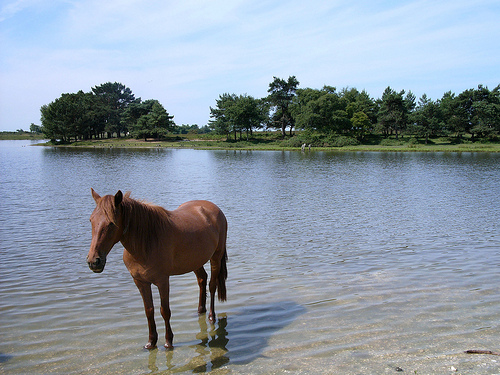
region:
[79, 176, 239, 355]
this is a horse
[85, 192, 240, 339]
the horse is brown in color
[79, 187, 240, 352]
the horse is standing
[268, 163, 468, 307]
the water is cam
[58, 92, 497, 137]
these are trees beside the water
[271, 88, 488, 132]
the trees are green in color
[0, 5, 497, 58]
the sky is light blue in color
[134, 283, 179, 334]
the horse has strong legs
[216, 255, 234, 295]
the tail is long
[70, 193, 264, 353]
the horse is in water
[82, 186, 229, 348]
Little brown pony.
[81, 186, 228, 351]
Horse standing in water.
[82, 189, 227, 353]
Little brown horse in lake.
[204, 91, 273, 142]
Tall dark green trees on bank.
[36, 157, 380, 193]
Dark calm waters of lake.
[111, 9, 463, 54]
Clear blue skies and light whispy clouds.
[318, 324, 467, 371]
Clear see through waters of lake.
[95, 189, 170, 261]
Horses beautiful brown mane.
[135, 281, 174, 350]
Two front legs of horse.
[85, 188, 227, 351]
Horse motionless in water.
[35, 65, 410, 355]
brown horse standing in the water.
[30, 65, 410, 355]
horse alone in the water.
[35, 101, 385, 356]
brown horse alone in water.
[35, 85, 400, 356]
beautiful horse in the water.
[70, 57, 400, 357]
attractive horse alone in the water.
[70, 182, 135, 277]
head of a horse.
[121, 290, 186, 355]
front legs of a horse.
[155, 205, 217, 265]
body of a horse.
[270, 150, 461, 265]
beautiful view of some water.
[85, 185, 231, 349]
Horse wading in water.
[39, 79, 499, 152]
Green trees in background.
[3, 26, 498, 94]
Sky is blue.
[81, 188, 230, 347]
Horse in water is brown.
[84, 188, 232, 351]
Horse standing still in water.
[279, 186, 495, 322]
Water is wavy.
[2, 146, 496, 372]
Brown horse standing in lake.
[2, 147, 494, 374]
Horse standing in lake.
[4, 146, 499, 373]
Horse standing at the edge of lake.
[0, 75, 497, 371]
Beautiful lake area.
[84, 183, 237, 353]
Brown horse standing in a body of water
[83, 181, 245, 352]
Brown horse standing alone in water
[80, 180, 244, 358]
Brown horse standing with hoofs in water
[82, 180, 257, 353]
Beautiful brown horse with brown mane and tail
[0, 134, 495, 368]
Body of water in a scenic area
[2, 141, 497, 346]
Body of water that the horse is standing in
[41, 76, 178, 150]
trees near a body of water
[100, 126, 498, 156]
Grassy area of land near a body of water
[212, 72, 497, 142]
forest of trees near a body of water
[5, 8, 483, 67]
nearly cloudless blue sky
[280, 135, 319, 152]
animals in the water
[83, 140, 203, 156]
ducks along water bank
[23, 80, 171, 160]
green big trees on island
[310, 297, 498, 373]
sand in water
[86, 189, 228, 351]
brown horse standing in water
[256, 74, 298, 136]
tallest tree in background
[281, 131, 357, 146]
bushes across the water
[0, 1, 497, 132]
blue sky with white clouds